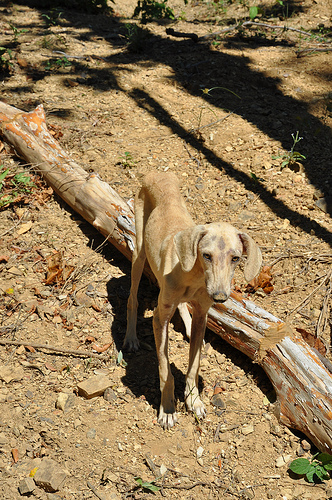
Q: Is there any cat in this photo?
A: No, there are no cats.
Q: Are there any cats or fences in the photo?
A: No, there are no cats or fences.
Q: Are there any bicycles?
A: No, there are no bicycles.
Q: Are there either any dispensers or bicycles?
A: No, there are no bicycles or dispensers.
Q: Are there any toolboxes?
A: No, there are no toolboxes.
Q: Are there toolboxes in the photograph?
A: No, there are no toolboxes.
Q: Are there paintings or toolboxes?
A: No, there are no toolboxes or paintings.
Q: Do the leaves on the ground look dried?
A: Yes, the leaves are dried.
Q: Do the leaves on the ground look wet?
A: No, the leaves are dried.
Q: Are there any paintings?
A: No, there are no paintings.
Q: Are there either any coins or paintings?
A: No, there are no paintings or coins.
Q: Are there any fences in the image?
A: No, there are no fences.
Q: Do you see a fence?
A: No, there are no fences.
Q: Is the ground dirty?
A: Yes, the ground is dirty.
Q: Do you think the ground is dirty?
A: Yes, the ground is dirty.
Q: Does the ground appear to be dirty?
A: Yes, the ground is dirty.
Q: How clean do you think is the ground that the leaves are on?
A: The ground is dirty.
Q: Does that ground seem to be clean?
A: No, the ground is dirty.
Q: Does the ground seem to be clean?
A: No, the ground is dirty.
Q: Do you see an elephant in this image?
A: No, there are no elephants.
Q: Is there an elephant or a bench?
A: No, there are no elephants or benches.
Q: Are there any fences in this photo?
A: No, there are no fences.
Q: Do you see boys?
A: No, there are no boys.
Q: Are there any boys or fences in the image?
A: No, there are no boys or fences.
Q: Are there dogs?
A: Yes, there is a dog.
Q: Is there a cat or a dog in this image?
A: Yes, there is a dog.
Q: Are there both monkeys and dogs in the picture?
A: No, there is a dog but no monkeys.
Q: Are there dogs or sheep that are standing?
A: Yes, the dog is standing.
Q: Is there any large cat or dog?
A: Yes, there is a large dog.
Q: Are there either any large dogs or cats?
A: Yes, there is a large dog.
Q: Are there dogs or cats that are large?
A: Yes, the dog is large.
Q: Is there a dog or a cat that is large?
A: Yes, the dog is large.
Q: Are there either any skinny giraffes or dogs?
A: Yes, there is a skinny dog.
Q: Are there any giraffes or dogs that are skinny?
A: Yes, the dog is skinny.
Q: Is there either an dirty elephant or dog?
A: Yes, there is a dirty dog.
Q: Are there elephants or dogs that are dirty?
A: Yes, the dog is dirty.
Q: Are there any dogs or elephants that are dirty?
A: Yes, the dog is dirty.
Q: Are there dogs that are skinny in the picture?
A: Yes, there is a skinny dog.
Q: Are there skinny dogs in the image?
A: Yes, there is a skinny dog.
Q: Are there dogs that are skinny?
A: Yes, there is a dog that is skinny.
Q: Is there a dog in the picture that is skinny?
A: Yes, there is a dog that is skinny.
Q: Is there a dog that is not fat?
A: Yes, there is a skinny dog.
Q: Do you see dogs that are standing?
A: Yes, there is a dog that is standing.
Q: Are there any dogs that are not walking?
A: Yes, there is a dog that is standing.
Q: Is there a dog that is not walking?
A: Yes, there is a dog that is standing.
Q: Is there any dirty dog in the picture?
A: Yes, there is a dirty dog.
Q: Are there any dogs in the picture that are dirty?
A: Yes, there is a dog that is dirty.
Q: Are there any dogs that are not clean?
A: Yes, there is a dirty dog.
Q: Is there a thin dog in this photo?
A: Yes, there is a thin dog.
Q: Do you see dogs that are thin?
A: Yes, there is a dog that is thin.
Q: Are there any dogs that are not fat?
A: Yes, there is a thin dog.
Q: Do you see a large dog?
A: Yes, there is a large dog.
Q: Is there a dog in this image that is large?
A: Yes, there is a dog that is large.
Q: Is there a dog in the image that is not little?
A: Yes, there is a large dog.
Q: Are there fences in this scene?
A: No, there are no fences.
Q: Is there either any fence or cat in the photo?
A: No, there are no fences or cats.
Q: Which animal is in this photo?
A: The animal is a dog.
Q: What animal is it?
A: The animal is a dog.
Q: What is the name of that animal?
A: This is a dog.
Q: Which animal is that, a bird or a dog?
A: This is a dog.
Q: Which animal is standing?
A: The animal is a dog.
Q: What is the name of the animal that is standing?
A: The animal is a dog.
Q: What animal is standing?
A: The animal is a dog.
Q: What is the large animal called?
A: The animal is a dog.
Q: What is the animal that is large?
A: The animal is a dog.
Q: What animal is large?
A: The animal is a dog.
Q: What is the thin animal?
A: The animal is a dog.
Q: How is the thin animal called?
A: The animal is a dog.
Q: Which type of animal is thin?
A: The animal is a dog.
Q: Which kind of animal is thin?
A: The animal is a dog.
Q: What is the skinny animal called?
A: The animal is a dog.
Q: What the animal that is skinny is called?
A: The animal is a dog.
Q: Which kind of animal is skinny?
A: The animal is a dog.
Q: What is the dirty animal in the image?
A: The animal is a dog.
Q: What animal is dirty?
A: The animal is a dog.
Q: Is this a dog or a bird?
A: This is a dog.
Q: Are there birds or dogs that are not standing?
A: No, there is a dog but it is standing.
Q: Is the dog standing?
A: Yes, the dog is standing.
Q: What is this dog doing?
A: The dog is standing.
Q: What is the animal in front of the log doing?
A: The dog is standing.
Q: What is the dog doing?
A: The dog is standing.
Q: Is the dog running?
A: No, the dog is standing.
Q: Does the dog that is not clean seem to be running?
A: No, the dog is standing.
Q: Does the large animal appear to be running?
A: No, the dog is standing.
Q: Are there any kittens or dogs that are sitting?
A: No, there is a dog but it is standing.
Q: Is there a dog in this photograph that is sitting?
A: No, there is a dog but it is standing.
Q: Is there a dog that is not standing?
A: No, there is a dog but it is standing.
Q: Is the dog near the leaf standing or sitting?
A: The dog is standing.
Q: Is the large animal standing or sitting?
A: The dog is standing.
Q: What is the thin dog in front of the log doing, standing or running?
A: The dog is standing.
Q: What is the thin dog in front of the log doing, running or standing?
A: The dog is standing.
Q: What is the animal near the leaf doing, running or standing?
A: The dog is standing.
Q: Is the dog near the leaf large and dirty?
A: Yes, the dog is large and dirty.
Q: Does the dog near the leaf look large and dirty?
A: Yes, the dog is large and dirty.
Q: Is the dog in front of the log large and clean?
A: No, the dog is large but dirty.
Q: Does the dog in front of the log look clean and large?
A: No, the dog is large but dirty.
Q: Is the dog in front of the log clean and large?
A: No, the dog is large but dirty.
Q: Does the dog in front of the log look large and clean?
A: No, the dog is large but dirty.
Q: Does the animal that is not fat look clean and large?
A: No, the dog is large but dirty.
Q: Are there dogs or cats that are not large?
A: No, there is a dog but it is large.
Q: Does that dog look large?
A: Yes, the dog is large.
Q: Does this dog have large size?
A: Yes, the dog is large.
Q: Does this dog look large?
A: Yes, the dog is large.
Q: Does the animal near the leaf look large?
A: Yes, the dog is large.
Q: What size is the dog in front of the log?
A: The dog is large.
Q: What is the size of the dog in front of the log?
A: The dog is large.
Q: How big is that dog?
A: The dog is large.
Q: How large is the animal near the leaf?
A: The dog is large.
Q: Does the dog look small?
A: No, the dog is large.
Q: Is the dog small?
A: No, the dog is large.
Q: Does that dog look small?
A: No, the dog is large.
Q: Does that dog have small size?
A: No, the dog is large.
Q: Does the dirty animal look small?
A: No, the dog is large.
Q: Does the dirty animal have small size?
A: No, the dog is large.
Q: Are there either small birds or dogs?
A: No, there is a dog but it is large.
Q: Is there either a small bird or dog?
A: No, there is a dog but it is large.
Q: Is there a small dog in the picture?
A: No, there is a dog but it is large.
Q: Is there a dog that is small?
A: No, there is a dog but it is large.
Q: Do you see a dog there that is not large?
A: No, there is a dog but it is large.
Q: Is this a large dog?
A: Yes, this is a large dog.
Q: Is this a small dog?
A: No, this is a large dog.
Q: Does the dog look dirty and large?
A: Yes, the dog is dirty and large.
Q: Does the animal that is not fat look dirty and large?
A: Yes, the dog is dirty and large.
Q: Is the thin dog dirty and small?
A: No, the dog is dirty but large.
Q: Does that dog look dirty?
A: Yes, the dog is dirty.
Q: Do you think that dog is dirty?
A: Yes, the dog is dirty.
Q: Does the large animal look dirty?
A: Yes, the dog is dirty.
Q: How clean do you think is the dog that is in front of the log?
A: The dog is dirty.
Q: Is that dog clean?
A: No, the dog is dirty.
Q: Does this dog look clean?
A: No, the dog is dirty.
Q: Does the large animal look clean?
A: No, the dog is dirty.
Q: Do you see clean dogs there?
A: No, there is a dog but it is dirty.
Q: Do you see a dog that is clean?
A: No, there is a dog but it is dirty.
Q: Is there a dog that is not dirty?
A: No, there is a dog but it is dirty.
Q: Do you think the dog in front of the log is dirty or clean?
A: The dog is dirty.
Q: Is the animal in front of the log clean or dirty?
A: The dog is dirty.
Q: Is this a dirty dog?
A: Yes, this is a dirty dog.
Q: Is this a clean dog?
A: No, this is a dirty dog.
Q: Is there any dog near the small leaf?
A: Yes, there is a dog near the leaf.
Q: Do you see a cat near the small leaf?
A: No, there is a dog near the leaf.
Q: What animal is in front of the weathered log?
A: The dog is in front of the log.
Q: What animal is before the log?
A: The dog is in front of the log.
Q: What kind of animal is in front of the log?
A: The animal is a dog.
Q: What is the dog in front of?
A: The dog is in front of the log.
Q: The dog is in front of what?
A: The dog is in front of the log.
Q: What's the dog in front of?
A: The dog is in front of the log.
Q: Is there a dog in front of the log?
A: Yes, there is a dog in front of the log.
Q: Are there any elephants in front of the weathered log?
A: No, there is a dog in front of the log.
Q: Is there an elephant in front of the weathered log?
A: No, there is a dog in front of the log.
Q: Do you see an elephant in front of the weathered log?
A: No, there is a dog in front of the log.